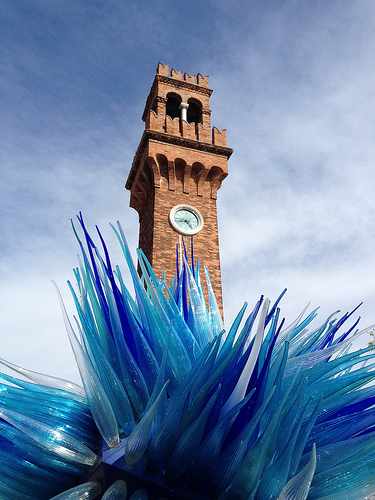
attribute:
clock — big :
[169, 202, 205, 238]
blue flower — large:
[38, 244, 329, 432]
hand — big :
[183, 218, 194, 229]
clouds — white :
[234, 78, 345, 228]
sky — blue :
[18, 17, 110, 136]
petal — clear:
[107, 217, 143, 301]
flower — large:
[57, 258, 282, 424]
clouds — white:
[219, 101, 372, 316]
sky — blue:
[4, 2, 373, 349]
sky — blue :
[26, 22, 120, 194]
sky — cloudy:
[265, 33, 346, 144]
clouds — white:
[217, 40, 372, 310]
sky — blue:
[194, 0, 374, 325]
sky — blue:
[0, 0, 182, 361]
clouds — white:
[0, 1, 375, 387]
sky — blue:
[0, 1, 375, 394]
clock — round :
[147, 184, 218, 234]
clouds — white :
[289, 20, 345, 110]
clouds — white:
[230, 184, 373, 282]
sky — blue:
[6, 1, 373, 58]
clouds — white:
[250, 92, 307, 146]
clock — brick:
[154, 196, 194, 241]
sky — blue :
[1, 0, 373, 132]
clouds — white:
[245, 219, 326, 287]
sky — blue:
[36, 28, 127, 103]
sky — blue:
[288, 45, 368, 146]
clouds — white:
[281, 81, 369, 167]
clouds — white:
[266, 158, 358, 334]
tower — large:
[99, 50, 278, 373]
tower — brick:
[107, 50, 267, 376]